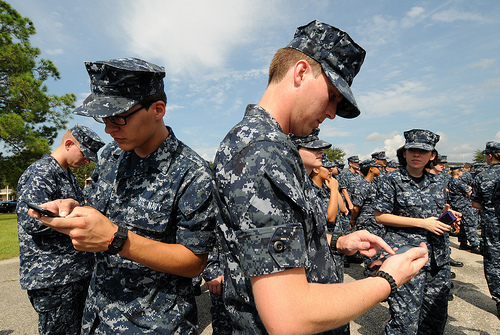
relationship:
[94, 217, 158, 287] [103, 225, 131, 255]
watch on a watch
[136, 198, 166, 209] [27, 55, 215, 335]
branch tape on a uniform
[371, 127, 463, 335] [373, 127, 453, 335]
navy member in a uniform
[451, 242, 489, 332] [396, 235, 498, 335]
shadow on asphalt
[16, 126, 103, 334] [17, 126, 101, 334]
man in uniform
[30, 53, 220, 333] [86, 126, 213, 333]
he in military uniform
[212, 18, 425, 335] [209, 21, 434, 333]
he in uniform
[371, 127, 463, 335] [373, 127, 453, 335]
navy member in uniform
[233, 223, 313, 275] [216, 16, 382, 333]
shirt cuff on military uniform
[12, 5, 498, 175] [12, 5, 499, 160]
clouds in clouds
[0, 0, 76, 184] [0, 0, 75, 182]
tree with leaves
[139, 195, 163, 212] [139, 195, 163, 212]
branch tape on branch tape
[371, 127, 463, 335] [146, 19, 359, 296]
navy member in uniform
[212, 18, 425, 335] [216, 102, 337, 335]
he in military uniform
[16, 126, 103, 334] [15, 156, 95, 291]
man in military uniform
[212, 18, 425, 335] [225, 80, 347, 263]
he in uniform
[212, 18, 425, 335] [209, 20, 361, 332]
he in a uniform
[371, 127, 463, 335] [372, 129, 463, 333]
navy member in a uniform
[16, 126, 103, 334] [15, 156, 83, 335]
man in a military uniform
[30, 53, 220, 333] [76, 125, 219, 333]
he in a uniform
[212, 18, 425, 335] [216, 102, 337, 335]
he in a military uniform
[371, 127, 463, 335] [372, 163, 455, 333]
navy member in a uniform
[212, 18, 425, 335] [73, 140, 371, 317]
he are wearing uniforms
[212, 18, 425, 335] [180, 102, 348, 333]
he are wearing uniforms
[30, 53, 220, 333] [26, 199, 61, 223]
he typing on cell phone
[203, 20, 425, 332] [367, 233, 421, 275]
he tapping on screen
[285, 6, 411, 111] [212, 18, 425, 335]
cap on he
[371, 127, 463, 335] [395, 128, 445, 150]
navy member wears cap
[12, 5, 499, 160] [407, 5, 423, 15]
clouds has cloud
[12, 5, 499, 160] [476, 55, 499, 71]
clouds has cloud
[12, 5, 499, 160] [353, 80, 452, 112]
clouds has cloud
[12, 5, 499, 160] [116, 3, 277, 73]
clouds has cloud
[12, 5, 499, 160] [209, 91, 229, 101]
clouds has cloud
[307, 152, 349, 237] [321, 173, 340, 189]
woman has hand